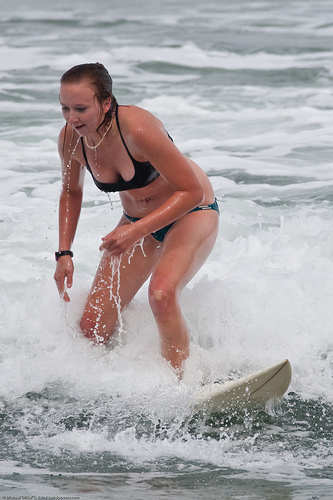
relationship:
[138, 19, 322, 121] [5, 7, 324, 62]
waves in ocean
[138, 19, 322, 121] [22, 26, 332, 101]
waves in ocean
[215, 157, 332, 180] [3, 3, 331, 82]
waves in ocean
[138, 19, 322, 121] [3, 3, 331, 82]
waves in ocean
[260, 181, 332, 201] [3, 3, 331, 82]
waves in ocean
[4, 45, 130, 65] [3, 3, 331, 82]
waves in ocean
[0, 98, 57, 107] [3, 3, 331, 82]
waves in ocean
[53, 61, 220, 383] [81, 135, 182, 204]
human in bikini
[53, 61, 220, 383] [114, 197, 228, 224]
human in bikini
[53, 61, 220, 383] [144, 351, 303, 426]
human on board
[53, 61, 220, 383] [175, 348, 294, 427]
human on surfboard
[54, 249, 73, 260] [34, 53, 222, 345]
watch of woman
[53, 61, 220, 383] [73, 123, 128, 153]
human wearing necklace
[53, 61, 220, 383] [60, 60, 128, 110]
human has hair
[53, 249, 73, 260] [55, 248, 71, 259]
watch on wrist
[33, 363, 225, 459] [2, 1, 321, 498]
water splash in water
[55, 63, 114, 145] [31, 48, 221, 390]
head on human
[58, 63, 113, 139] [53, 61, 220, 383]
head of human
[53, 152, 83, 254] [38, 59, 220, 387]
arm of woman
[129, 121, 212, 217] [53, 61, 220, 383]
arm of human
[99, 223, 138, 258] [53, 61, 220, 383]
hand of human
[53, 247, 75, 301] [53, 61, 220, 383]
hand of human